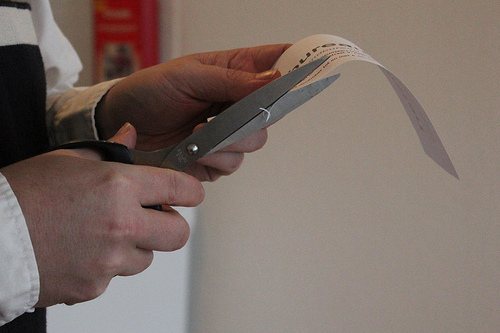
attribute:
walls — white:
[50, 3, 500, 332]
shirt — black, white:
[2, 2, 119, 240]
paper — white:
[247, 33, 469, 183]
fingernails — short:
[256, 67, 281, 80]